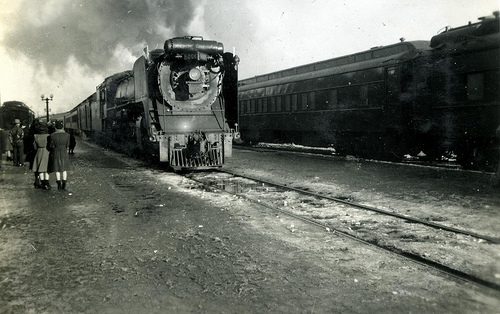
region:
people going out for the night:
[9, 119, 79, 185]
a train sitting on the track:
[32, 42, 242, 171]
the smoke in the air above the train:
[7, 3, 184, 50]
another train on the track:
[239, 15, 498, 179]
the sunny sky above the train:
[234, 3, 453, 54]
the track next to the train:
[193, 169, 499, 292]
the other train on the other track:
[2, 99, 36, 124]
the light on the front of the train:
[183, 64, 205, 100]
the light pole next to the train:
[36, 92, 56, 112]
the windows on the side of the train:
[239, 86, 384, 116]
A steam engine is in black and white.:
[111, 10, 252, 169]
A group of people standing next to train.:
[1, 106, 84, 191]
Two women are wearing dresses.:
[20, 126, 95, 183]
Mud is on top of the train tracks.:
[199, 161, 461, 286]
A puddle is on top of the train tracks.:
[193, 170, 262, 200]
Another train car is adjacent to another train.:
[256, 68, 471, 153]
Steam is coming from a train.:
[78, 4, 194, 60]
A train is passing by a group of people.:
[11, 79, 128, 218]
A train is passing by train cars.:
[138, 55, 395, 175]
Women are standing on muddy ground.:
[31, 124, 101, 207]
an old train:
[64, 28, 252, 177]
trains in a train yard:
[5, 18, 499, 226]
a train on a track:
[75, 30, 367, 270]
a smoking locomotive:
[92, 34, 242, 174]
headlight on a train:
[187, 65, 204, 85]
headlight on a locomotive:
[181, 67, 208, 84]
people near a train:
[5, 111, 80, 194]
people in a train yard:
[6, 110, 74, 197]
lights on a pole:
[38, 88, 56, 125]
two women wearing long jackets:
[28, 122, 74, 192]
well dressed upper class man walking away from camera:
[49, 116, 71, 193]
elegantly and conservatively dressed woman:
[29, 123, 51, 193]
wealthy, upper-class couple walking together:
[30, 114, 70, 192]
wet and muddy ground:
[18, 210, 375, 310]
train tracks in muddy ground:
[212, 180, 498, 301]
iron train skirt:
[165, 136, 225, 171]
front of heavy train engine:
[141, 36, 231, 114]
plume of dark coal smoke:
[0, 2, 203, 37]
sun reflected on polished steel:
[160, 115, 222, 130]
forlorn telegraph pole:
[38, 90, 55, 116]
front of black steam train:
[142, 35, 239, 177]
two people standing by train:
[24, 119, 71, 206]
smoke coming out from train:
[15, 2, 205, 59]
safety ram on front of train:
[177, 145, 220, 167]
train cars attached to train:
[52, 94, 99, 126]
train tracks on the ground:
[247, 172, 400, 244]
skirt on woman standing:
[31, 148, 46, 176]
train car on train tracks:
[242, 49, 436, 137]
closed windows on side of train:
[255, 79, 370, 119]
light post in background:
[40, 93, 52, 102]